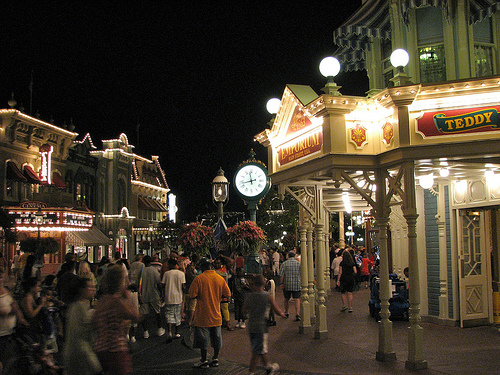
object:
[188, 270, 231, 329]
yellow shirt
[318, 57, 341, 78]
light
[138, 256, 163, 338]
man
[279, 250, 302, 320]
man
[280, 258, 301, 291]
blue shirt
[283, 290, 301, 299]
shorts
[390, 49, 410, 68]
lights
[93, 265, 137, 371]
person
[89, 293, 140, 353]
clothes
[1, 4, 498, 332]
town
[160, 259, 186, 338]
person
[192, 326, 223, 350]
blue shorts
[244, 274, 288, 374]
people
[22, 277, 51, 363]
people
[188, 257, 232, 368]
man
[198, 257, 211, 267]
hat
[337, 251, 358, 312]
woman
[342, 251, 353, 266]
hair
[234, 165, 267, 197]
clock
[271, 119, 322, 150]
lights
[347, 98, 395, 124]
lights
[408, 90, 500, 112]
lights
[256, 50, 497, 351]
stores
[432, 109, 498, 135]
sign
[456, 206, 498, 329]
door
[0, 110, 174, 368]
building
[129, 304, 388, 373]
street